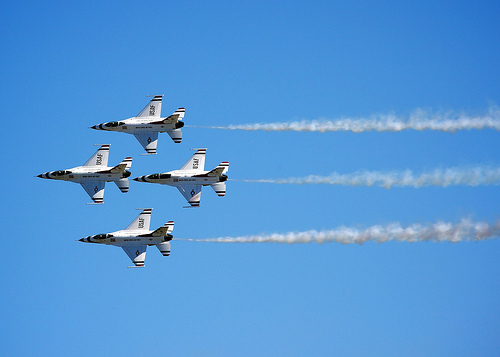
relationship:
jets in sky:
[34, 94, 229, 272] [1, 2, 500, 357]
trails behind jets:
[172, 101, 499, 246] [34, 94, 229, 272]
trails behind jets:
[175, 105, 499, 259] [34, 94, 229, 272]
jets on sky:
[34, 94, 229, 272] [1, 2, 500, 357]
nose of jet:
[37, 169, 49, 181] [34, 144, 132, 205]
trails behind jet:
[172, 101, 499, 246] [88, 93, 186, 154]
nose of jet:
[89, 124, 105, 133] [88, 93, 186, 154]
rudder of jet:
[108, 164, 129, 174] [34, 144, 132, 205]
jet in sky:
[34, 144, 132, 205] [1, 2, 500, 357]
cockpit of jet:
[54, 170, 73, 177] [34, 144, 132, 205]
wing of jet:
[78, 183, 105, 203] [34, 144, 132, 205]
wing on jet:
[78, 183, 105, 203] [34, 144, 132, 205]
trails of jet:
[172, 101, 499, 246] [88, 93, 186, 154]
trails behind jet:
[175, 105, 499, 259] [34, 144, 132, 205]